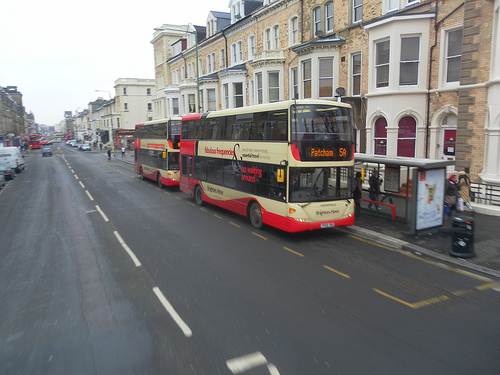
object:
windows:
[273, 108, 288, 141]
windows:
[231, 114, 253, 142]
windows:
[202, 115, 224, 141]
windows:
[181, 120, 190, 140]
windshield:
[288, 165, 355, 203]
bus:
[180, 99, 356, 233]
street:
[240, 238, 499, 375]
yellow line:
[371, 287, 412, 309]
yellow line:
[322, 264, 351, 279]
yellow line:
[283, 246, 304, 257]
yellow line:
[252, 231, 268, 240]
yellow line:
[228, 221, 240, 228]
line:
[152, 285, 194, 337]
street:
[0, 144, 200, 373]